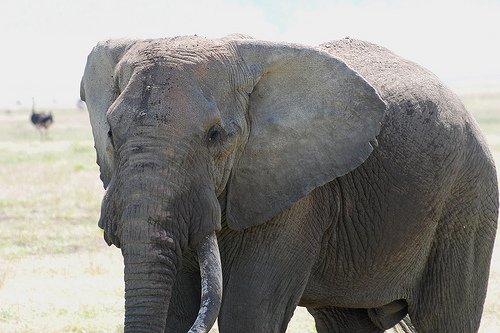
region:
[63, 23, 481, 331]
a big elephant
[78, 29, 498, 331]
he appears to be very old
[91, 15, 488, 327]
he is very wrinkled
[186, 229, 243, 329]
he has a very large tusk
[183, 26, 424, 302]
his ear is very large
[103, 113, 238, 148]
his eyes are small compared to the rest of his size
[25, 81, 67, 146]
two ostrich or emus stand in the background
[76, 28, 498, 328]
the elephant is grey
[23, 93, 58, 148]
the birds are tall & have long necks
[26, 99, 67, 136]
their body is black & brown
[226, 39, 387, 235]
An elephants ear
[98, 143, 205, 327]
The trunk of an elephant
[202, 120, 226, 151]
The eye of an elephant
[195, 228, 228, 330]
The tusk of an elephant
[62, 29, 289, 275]
The face of an elephant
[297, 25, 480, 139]
The back of an elephant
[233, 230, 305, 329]
The front leg of an elephant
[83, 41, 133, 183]
The ear of an elephant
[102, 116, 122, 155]
The eye of an elephant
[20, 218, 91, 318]
A grassy field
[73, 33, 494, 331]
Elephant standing in the forest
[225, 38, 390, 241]
Big size ear of the elephant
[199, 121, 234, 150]
Eye of the elephant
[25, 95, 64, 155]
Bird standing in the forest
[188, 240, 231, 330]
Tusk of the elephant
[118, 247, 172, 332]
Trunk of the elephant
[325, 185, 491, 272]
Grey color wrinkled skin of the elephant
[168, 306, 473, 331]
Legs of the elephant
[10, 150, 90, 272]
Green color grass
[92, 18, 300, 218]
Head portion of the elephant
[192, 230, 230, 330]
The tusk of the elephant.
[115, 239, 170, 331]
The trunk of the elephant.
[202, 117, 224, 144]
The right eye of the elephant.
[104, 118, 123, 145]
The left eye of the elephant.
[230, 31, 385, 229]
The right ear of the elephant.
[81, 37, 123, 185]
The left ear of the elephant.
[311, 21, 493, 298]
The body of the elephant.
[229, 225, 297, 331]
The right front leg of the elephant.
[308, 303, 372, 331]
The back left leg of the elephant.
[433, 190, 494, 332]
The back right thigh of the elephant.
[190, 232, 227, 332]
White brown and gray elephant tusk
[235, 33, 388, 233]
Large gray adult elephant ear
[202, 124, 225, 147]
Dark black eye of an adult elephant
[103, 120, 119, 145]
Side of eye of an adult elephant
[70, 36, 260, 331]
Head and tusk of an adult elephant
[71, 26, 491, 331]
Adult elephant in the planes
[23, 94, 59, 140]
black and white ostrich in the background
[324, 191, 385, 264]
Wrinkles on the side of the adult elephant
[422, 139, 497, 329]
Hind leg of adult elephant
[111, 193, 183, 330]
Long nose of adult elephant